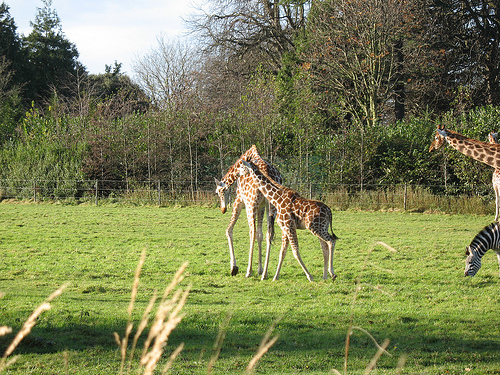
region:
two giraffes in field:
[161, 153, 334, 279]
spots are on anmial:
[250, 164, 326, 233]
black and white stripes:
[456, 215, 499, 288]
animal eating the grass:
[458, 228, 499, 283]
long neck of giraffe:
[428, 128, 498, 168]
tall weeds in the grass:
[103, 248, 188, 366]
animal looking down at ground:
[205, 145, 258, 254]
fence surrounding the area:
[1, 148, 216, 217]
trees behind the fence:
[29, 65, 414, 158]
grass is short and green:
[1, 200, 213, 307]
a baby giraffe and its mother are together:
[206, 133, 345, 290]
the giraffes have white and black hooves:
[227, 263, 337, 288]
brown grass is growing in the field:
[8, 250, 426, 374]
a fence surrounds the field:
[5, 163, 498, 219]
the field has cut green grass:
[7, 203, 497, 369]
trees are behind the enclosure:
[11, 14, 492, 201]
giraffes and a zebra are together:
[426, 120, 498, 285]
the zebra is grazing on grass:
[454, 219, 497, 285]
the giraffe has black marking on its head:
[423, 119, 475, 168]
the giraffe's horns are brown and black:
[433, 120, 449, 135]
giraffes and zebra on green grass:
[26, 111, 493, 351]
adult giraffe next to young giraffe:
[210, 130, 340, 280]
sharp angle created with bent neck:
[210, 135, 265, 210]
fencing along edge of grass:
[5, 166, 486, 211]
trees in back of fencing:
[5, 2, 485, 207]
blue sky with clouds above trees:
[5, 1, 305, 106]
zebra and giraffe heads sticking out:
[412, 115, 494, 285]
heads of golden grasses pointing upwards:
[5, 240, 440, 370]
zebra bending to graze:
[460, 217, 495, 284]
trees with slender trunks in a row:
[95, 105, 200, 201]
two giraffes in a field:
[200, 138, 355, 298]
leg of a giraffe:
[290, 233, 313, 329]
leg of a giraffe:
[270, 241, 285, 287]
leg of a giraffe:
[240, 220, 262, 316]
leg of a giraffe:
[215, 215, 246, 295]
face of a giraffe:
[210, 158, 231, 214]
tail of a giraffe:
[325, 207, 345, 238]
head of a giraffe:
[415, 120, 467, 170]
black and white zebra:
[455, 226, 485, 281]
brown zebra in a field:
[410, 111, 483, 177]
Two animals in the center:
[185, 125, 371, 294]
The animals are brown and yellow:
[187, 135, 368, 305]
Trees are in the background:
[210, 3, 496, 225]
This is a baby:
[236, 156, 365, 274]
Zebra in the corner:
[451, 220, 498, 276]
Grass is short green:
[24, 202, 171, 264]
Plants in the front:
[2, 250, 496, 373]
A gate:
[4, 149, 485, 226]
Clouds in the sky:
[73, 6, 162, 61]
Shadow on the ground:
[48, 274, 404, 357]